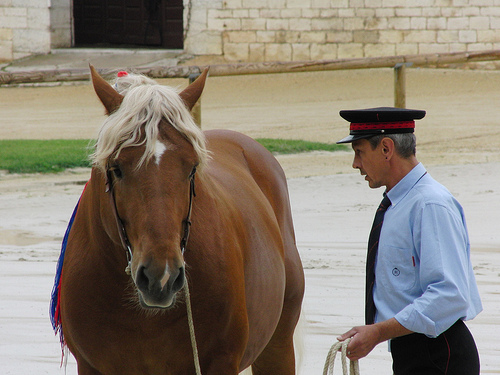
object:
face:
[100, 95, 211, 307]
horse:
[53, 62, 306, 373]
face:
[353, 143, 384, 184]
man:
[339, 105, 480, 374]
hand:
[336, 322, 382, 362]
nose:
[135, 256, 188, 311]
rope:
[322, 334, 360, 375]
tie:
[364, 199, 397, 335]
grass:
[0, 134, 349, 172]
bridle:
[104, 157, 201, 267]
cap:
[333, 106, 427, 146]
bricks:
[224, 40, 251, 61]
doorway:
[70, 2, 184, 48]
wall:
[3, 0, 497, 70]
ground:
[0, 161, 499, 374]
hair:
[89, 86, 210, 170]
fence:
[1, 67, 498, 147]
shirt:
[363, 163, 481, 338]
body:
[55, 128, 307, 374]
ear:
[380, 137, 395, 162]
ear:
[87, 63, 127, 114]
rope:
[181, 268, 357, 375]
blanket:
[49, 166, 97, 369]